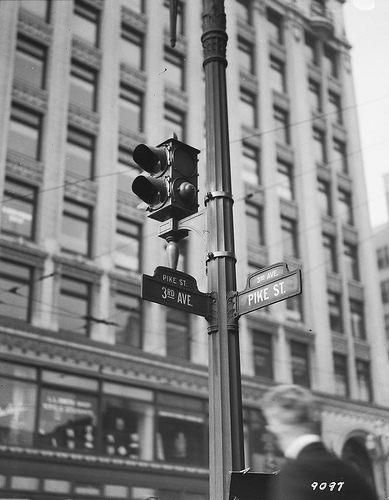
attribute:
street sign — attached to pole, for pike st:
[236, 261, 309, 318]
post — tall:
[201, 3, 248, 499]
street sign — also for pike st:
[139, 265, 208, 319]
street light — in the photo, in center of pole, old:
[131, 129, 202, 238]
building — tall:
[1, 2, 388, 496]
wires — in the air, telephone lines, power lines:
[1, 90, 389, 325]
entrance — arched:
[337, 426, 388, 497]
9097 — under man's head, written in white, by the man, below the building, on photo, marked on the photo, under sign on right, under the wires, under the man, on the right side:
[309, 480, 343, 492]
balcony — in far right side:
[307, 0, 337, 34]